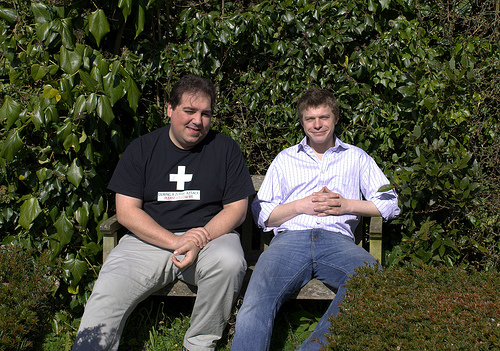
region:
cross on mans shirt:
[157, 161, 202, 192]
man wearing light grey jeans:
[110, 253, 132, 299]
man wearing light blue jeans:
[278, 245, 301, 285]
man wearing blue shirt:
[201, 154, 233, 179]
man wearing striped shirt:
[286, 159, 311, 179]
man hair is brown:
[306, 91, 326, 103]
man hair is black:
[176, 80, 202, 90]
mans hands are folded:
[302, 178, 352, 226]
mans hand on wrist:
[183, 224, 218, 252]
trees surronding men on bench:
[19, 87, 82, 184]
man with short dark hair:
[256, 48, 379, 174]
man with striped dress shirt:
[264, 63, 361, 190]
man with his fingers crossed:
[250, 82, 403, 258]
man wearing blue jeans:
[209, 202, 375, 349]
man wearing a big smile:
[218, 83, 372, 228]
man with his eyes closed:
[83, 49, 247, 180]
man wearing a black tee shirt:
[85, 47, 302, 271]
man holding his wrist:
[73, 59, 269, 341]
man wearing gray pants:
[73, 226, 258, 349]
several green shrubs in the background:
[0, 28, 447, 340]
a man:
[252, 30, 387, 329]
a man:
[246, 51, 316, 331]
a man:
[279, 150, 334, 346]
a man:
[298, 68, 368, 342]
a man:
[296, 124, 326, 326]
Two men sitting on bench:
[109, 70, 399, 327]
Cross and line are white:
[154, 162, 214, 208]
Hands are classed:
[308, 180, 348, 220]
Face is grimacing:
[291, 78, 349, 142]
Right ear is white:
[161, 95, 178, 124]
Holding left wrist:
[161, 223, 221, 263]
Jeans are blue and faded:
[256, 222, 380, 344]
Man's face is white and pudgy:
[161, 72, 226, 141]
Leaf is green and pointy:
[83, 7, 114, 49]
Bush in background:
[186, 4, 496, 253]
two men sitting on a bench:
[73, 78, 405, 349]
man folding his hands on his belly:
[254, 87, 381, 348]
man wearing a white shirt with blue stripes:
[267, 130, 399, 248]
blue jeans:
[248, 230, 370, 349]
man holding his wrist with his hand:
[123, 197, 235, 277]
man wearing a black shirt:
[116, 141, 248, 242]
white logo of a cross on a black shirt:
[145, 152, 212, 219]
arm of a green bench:
[361, 215, 401, 261]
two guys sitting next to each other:
[91, 77, 394, 336]